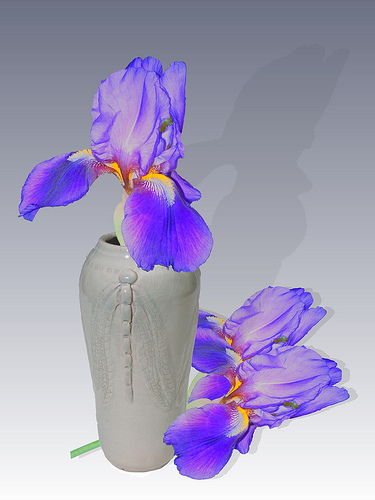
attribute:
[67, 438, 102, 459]
stem — green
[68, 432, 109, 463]
stem — green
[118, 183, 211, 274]
petal — purple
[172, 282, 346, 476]
petals — purple, yellow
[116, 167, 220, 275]
petal — purple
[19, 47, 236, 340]
vase — grey, stone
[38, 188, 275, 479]
vase — stone, grey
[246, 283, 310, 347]
flower — purple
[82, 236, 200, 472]
vase — grey, gray, stone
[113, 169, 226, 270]
petal — purple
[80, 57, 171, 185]
petal — purple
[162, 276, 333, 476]
flowers — laying down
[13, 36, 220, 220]
iris — purple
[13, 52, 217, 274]
flowers — purple, yellow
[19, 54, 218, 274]
flower — purple, yellow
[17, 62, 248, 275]
flower — purple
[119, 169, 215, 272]
petal — purple, yellow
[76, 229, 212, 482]
vase — grey, stone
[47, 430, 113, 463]
stem — green